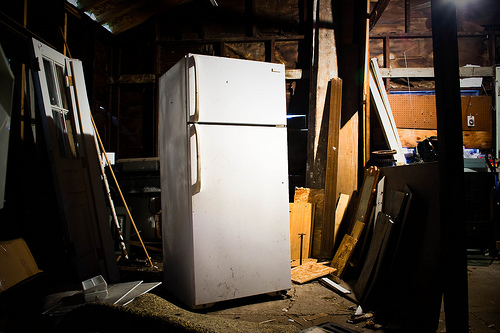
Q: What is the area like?
A: Cluttered.